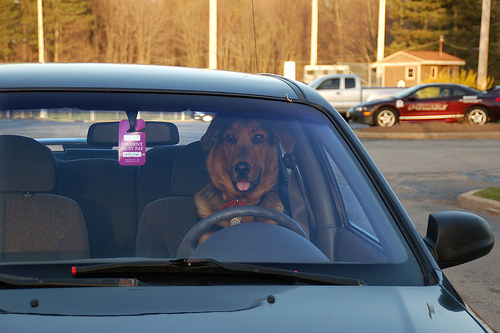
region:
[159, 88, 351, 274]
dog in driver's seat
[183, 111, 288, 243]
dog wearing red collar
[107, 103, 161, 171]
hanging purple parking permit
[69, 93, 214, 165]
permit hanging from mirror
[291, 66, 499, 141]
car and truck on road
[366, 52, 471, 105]
small house beside road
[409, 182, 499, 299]
side view mirror on car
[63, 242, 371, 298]
windshield wiper on car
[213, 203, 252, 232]
dog wearing dog tag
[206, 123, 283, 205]
dog with tongue hanging out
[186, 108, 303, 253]
large dog sitting behind steering wheel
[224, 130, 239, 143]
right eye of dog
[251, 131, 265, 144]
left eye of dog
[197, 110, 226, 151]
right ear of dog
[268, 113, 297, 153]
left ear of dog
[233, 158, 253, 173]
black nose of dog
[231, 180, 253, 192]
pink tongue of dog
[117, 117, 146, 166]
purple parking permit on rear view mirror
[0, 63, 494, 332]
dark car the dog is sitting in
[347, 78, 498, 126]
red car parked in the background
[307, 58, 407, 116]
silver truck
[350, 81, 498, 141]
red compact car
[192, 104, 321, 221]
black and brown dog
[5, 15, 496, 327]
black and brown dog sitting in drivers seat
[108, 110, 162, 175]
parking permit hang tag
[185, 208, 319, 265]
gray steering wheel in car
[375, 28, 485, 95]
brown and white house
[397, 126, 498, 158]
cement curb in parking lot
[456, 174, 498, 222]
cement curb with grass in parking lot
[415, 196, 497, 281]
side review mirror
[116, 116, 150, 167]
purple parking pass hanging on mirror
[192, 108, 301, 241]
dog sitting behind a steering wheel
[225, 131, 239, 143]
right eye of dog in car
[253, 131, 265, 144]
left eye of dog in car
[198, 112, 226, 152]
right ear of dog in car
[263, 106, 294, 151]
left ear of dog in car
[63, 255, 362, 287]
drivers wiper blade with red tip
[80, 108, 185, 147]
rear view mirror hanging from windshield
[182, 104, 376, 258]
Dog in the car.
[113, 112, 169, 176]
Purple sign on the mirror.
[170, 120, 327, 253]
Dog behind the wheel.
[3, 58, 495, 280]
Car on the road.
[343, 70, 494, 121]
Red car in the background.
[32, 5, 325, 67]
Trees in the background.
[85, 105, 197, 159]
Mirror with purple sign.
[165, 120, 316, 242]
Beige and black dog.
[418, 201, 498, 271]
Black mirror on car.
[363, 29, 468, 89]
House behind the car.